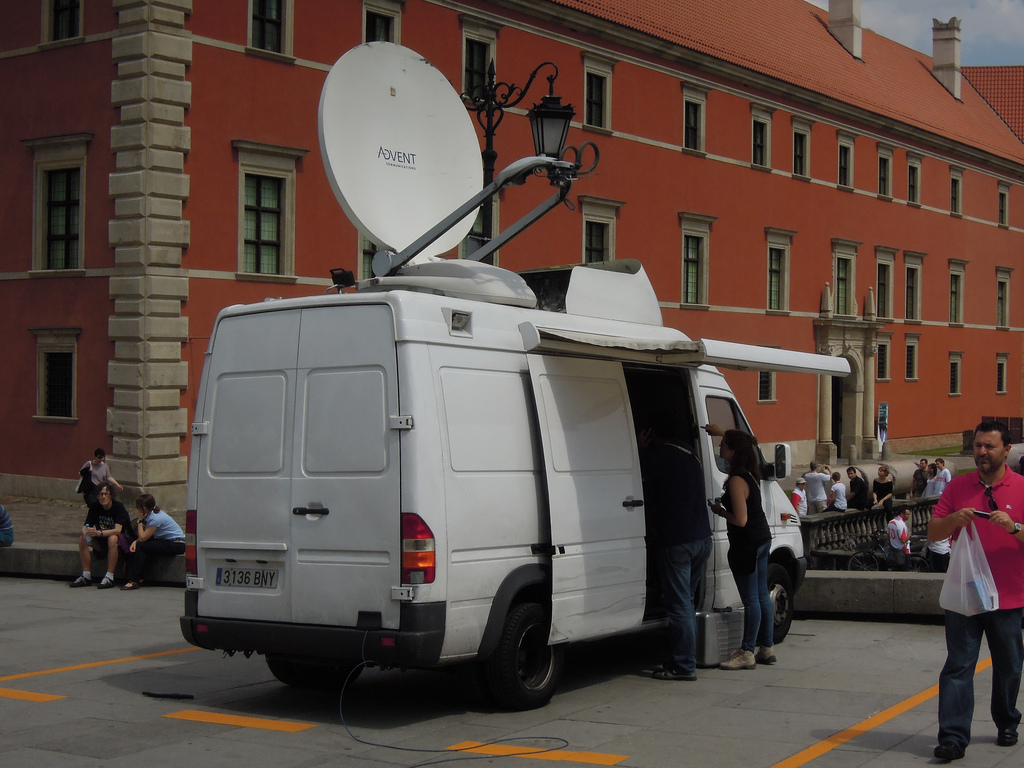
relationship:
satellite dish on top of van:
[324, 39, 476, 258] [187, 281, 818, 667]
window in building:
[582, 74, 617, 139] [5, 3, 1023, 535]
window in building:
[685, 232, 708, 300] [5, 3, 1023, 535]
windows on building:
[724, 245, 839, 367] [183, 19, 952, 648]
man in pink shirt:
[928, 424, 1023, 758] [933, 468, 1024, 610]